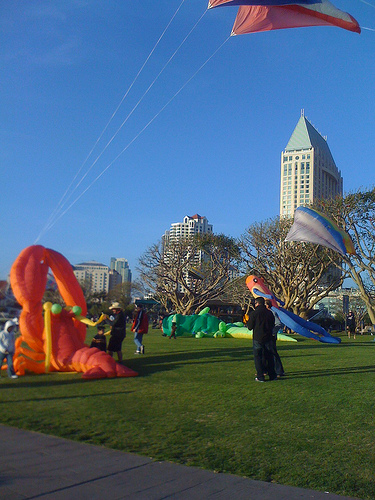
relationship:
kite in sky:
[205, 1, 364, 40] [1, 1, 374, 296]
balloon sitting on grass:
[10, 244, 139, 379] [2, 322, 375, 500]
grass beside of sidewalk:
[2, 322, 375, 500] [0, 419, 352, 498]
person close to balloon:
[101, 300, 124, 362] [10, 244, 139, 379]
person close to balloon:
[90, 324, 107, 349] [10, 244, 139, 379]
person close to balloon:
[1, 319, 19, 380] [10, 244, 139, 379]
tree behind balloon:
[132, 229, 241, 315] [160, 306, 300, 341]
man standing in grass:
[242, 296, 276, 382] [2, 322, 375, 500]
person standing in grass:
[101, 300, 124, 362] [2, 322, 375, 500]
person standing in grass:
[90, 324, 107, 349] [2, 322, 375, 500]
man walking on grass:
[242, 296, 276, 382] [2, 322, 375, 500]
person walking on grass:
[101, 300, 124, 362] [2, 322, 375, 500]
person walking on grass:
[90, 324, 107, 349] [2, 322, 375, 500]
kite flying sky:
[205, 1, 364, 40] [1, 1, 374, 296]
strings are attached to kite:
[32, 1, 233, 245] [205, 1, 364, 40]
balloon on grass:
[160, 306, 300, 341] [2, 322, 375, 500]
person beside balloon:
[90, 324, 107, 349] [10, 244, 139, 379]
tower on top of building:
[281, 107, 330, 151] [279, 107, 341, 323]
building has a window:
[279, 107, 341, 323] [283, 153, 288, 161]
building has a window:
[279, 107, 341, 323] [286, 154, 292, 164]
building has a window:
[279, 107, 341, 323] [300, 152, 306, 160]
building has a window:
[279, 107, 341, 323] [305, 153, 311, 159]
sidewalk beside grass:
[0, 419, 352, 498] [2, 322, 375, 500]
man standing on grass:
[242, 296, 276, 382] [2, 322, 375, 500]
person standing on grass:
[101, 300, 124, 362] [2, 322, 375, 500]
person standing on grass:
[90, 324, 107, 349] [2, 322, 375, 500]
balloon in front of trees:
[283, 205, 358, 261] [89, 190, 374, 334]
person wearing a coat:
[127, 300, 148, 358] [128, 309, 149, 334]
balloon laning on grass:
[160, 306, 300, 341] [2, 322, 375, 500]